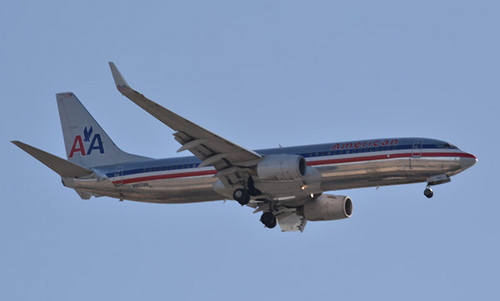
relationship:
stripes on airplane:
[104, 149, 474, 186] [9, 61, 478, 233]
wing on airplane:
[105, 62, 258, 172] [13, 53, 481, 230]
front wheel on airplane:
[422, 185, 435, 203] [9, 61, 478, 233]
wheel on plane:
[231, 184, 250, 207] [2, 61, 489, 253]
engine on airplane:
[255, 151, 305, 182] [9, 61, 478, 233]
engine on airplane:
[299, 193, 351, 221] [9, 61, 478, 233]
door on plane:
[413, 136, 421, 177] [154, 93, 486, 233]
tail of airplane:
[57, 92, 155, 167] [9, 61, 478, 233]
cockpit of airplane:
[447, 140, 466, 159] [9, 61, 478, 233]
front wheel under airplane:
[424, 188, 433, 197] [9, 61, 478, 233]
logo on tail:
[58, 117, 127, 165] [17, 88, 137, 211]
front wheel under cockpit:
[424, 188, 433, 197] [395, 105, 480, 222]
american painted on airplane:
[330, 135, 399, 150] [9, 61, 478, 233]